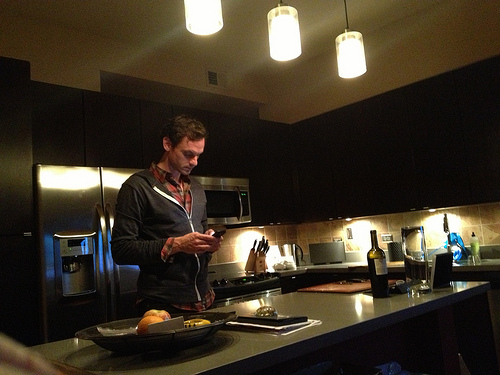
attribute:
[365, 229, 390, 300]
bottle — large, tall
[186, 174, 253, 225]
microwave — black, silver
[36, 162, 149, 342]
refrigerator — silver, two-door, large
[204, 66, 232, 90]
vent — white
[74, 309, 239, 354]
bowl — shallow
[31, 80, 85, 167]
cabinet door — brown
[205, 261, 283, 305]
stove — silver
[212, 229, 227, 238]
cell phone — black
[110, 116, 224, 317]
man — standing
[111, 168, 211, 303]
jacket — black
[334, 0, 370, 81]
light — hanging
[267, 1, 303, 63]
light — hanging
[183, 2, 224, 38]
light — hanging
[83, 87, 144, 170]
cabinet door — dark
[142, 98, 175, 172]
cabinet door — dark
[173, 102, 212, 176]
cabinet door — dark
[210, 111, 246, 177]
cabinet door — dark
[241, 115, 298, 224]
cabinet door — dark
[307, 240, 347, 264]
toaster — stainless steel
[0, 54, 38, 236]
cabinet door — dark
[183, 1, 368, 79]
lights — modern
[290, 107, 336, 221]
cabinet door — dark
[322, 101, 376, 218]
cabinet door — dark